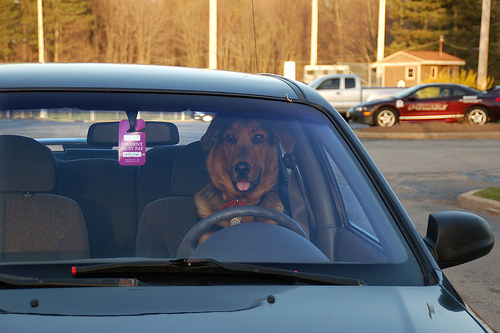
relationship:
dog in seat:
[193, 117, 295, 253] [134, 139, 210, 257]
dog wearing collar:
[193, 117, 295, 253] [219, 201, 256, 222]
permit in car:
[117, 119, 147, 166] [0, 62, 498, 332]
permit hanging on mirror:
[117, 119, 147, 166] [88, 110, 178, 146]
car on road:
[345, 82, 499, 124] [127, 113, 500, 333]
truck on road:
[307, 72, 413, 113] [127, 113, 500, 333]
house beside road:
[371, 36, 466, 87] [127, 113, 500, 333]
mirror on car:
[422, 212, 492, 270] [0, 62, 498, 332]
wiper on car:
[70, 257, 359, 286] [0, 62, 498, 332]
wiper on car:
[1, 273, 97, 286] [0, 62, 498, 332]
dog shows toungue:
[193, 117, 295, 253] [236, 181, 251, 192]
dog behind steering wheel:
[193, 117, 295, 253] [176, 203, 309, 258]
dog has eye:
[193, 117, 295, 253] [252, 134, 266, 145]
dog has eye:
[193, 117, 295, 253] [224, 134, 238, 145]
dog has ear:
[193, 117, 295, 253] [198, 112, 230, 149]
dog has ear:
[193, 117, 295, 253] [275, 122, 297, 155]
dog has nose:
[193, 117, 295, 253] [236, 163, 251, 176]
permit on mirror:
[117, 119, 147, 166] [88, 110, 178, 146]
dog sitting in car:
[193, 117, 295, 253] [0, 62, 498, 332]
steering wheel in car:
[176, 203, 309, 258] [0, 62, 498, 332]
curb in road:
[456, 189, 499, 209] [127, 113, 500, 333]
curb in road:
[357, 127, 499, 141] [127, 113, 500, 333]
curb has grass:
[456, 189, 499, 209] [476, 191, 500, 200]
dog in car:
[193, 117, 295, 253] [0, 62, 498, 332]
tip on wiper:
[70, 268, 77, 276] [70, 257, 359, 286]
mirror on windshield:
[88, 110, 178, 146] [2, 92, 424, 287]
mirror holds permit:
[88, 110, 178, 146] [117, 119, 147, 166]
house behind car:
[371, 36, 466, 87] [345, 82, 499, 124]